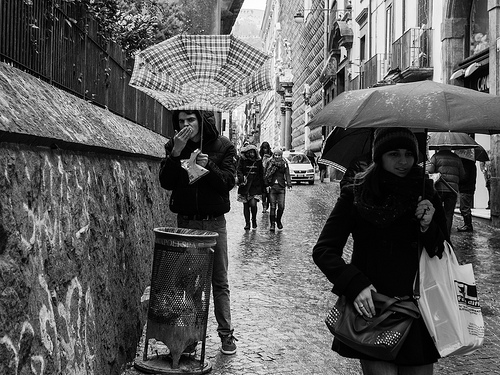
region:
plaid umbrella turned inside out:
[128, 28, 275, 114]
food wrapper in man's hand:
[178, 147, 208, 184]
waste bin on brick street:
[140, 220, 216, 373]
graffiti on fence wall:
[5, 142, 112, 372]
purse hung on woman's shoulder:
[325, 277, 423, 359]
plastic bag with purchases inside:
[411, 235, 486, 361]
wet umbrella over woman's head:
[298, 70, 498, 135]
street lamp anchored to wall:
[290, 2, 350, 27]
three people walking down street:
[235, 135, 288, 241]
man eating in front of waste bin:
[155, 100, 246, 359]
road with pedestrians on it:
[225, 162, 470, 353]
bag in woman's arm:
[420, 241, 485, 349]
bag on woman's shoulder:
[321, 291, 430, 372]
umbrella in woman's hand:
[315, 71, 485, 225]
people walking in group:
[238, 138, 295, 228]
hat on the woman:
[367, 122, 420, 156]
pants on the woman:
[266, 182, 291, 216]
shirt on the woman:
[240, 193, 259, 198]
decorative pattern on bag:
[375, 330, 400, 350]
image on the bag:
[451, 275, 478, 305]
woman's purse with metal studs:
[319, 283, 420, 363]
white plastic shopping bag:
[414, 233, 488, 356]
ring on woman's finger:
[357, 303, 365, 310]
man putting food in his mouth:
[154, 106, 234, 213]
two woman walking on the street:
[230, 144, 292, 234]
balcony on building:
[387, 27, 437, 78]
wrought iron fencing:
[0, 0, 162, 118]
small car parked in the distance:
[280, 147, 320, 183]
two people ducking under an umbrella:
[425, 127, 485, 237]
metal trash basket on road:
[135, 225, 210, 373]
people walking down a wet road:
[235, 141, 290, 231]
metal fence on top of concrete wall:
[1, 1, 173, 138]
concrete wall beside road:
[1, 63, 176, 374]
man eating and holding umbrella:
[128, 32, 277, 356]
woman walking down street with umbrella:
[306, 78, 499, 374]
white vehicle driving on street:
[279, 147, 314, 185]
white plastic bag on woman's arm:
[413, 242, 484, 358]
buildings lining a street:
[241, 1, 499, 227]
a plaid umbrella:
[109, 12, 324, 152]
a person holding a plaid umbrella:
[95, 22, 277, 213]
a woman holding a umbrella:
[311, 52, 494, 237]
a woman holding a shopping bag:
[326, 90, 491, 370]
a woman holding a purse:
[310, 105, 451, 365]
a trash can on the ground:
[119, 210, 271, 374]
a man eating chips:
[132, 105, 224, 198]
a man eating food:
[153, 97, 279, 240]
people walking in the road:
[233, 135, 333, 236]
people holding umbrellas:
[103, 14, 497, 197]